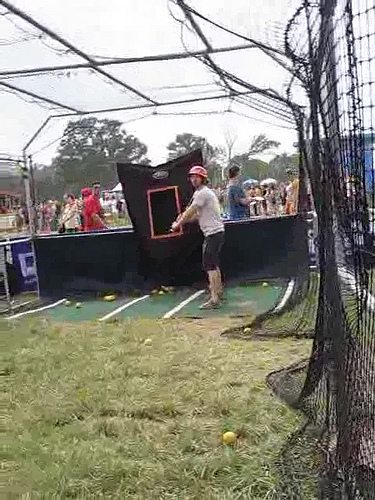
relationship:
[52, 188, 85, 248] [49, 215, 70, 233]
woman holds a purse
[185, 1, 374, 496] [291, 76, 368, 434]
mesh at side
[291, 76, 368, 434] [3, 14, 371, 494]
side of pen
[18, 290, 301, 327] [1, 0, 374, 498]
ground of enclosure